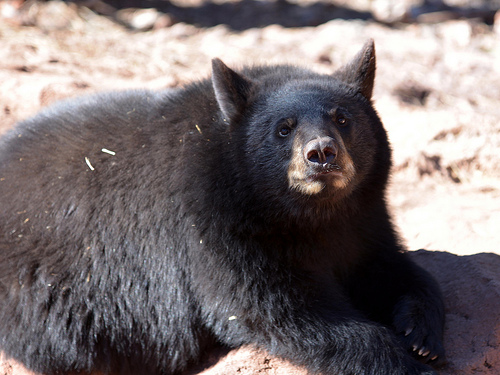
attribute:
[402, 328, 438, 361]
nails —  bear's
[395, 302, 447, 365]
paw —  bear's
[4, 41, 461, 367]
bear —   in   wild,  relaxed,  calm,  big,  black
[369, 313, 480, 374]
paw — the front left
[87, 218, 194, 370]
fur —  bear's,  black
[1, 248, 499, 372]
platform —  rocky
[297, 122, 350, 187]
nose —  bear's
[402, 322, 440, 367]
claws — cut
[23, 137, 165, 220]
fur —  with stuff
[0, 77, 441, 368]
bear —  furry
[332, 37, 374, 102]
ears — triangular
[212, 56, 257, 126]
ears — triangular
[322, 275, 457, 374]
bear's paws —  black,   bear's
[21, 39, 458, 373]
fur — light brown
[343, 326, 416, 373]
paw — the front  right